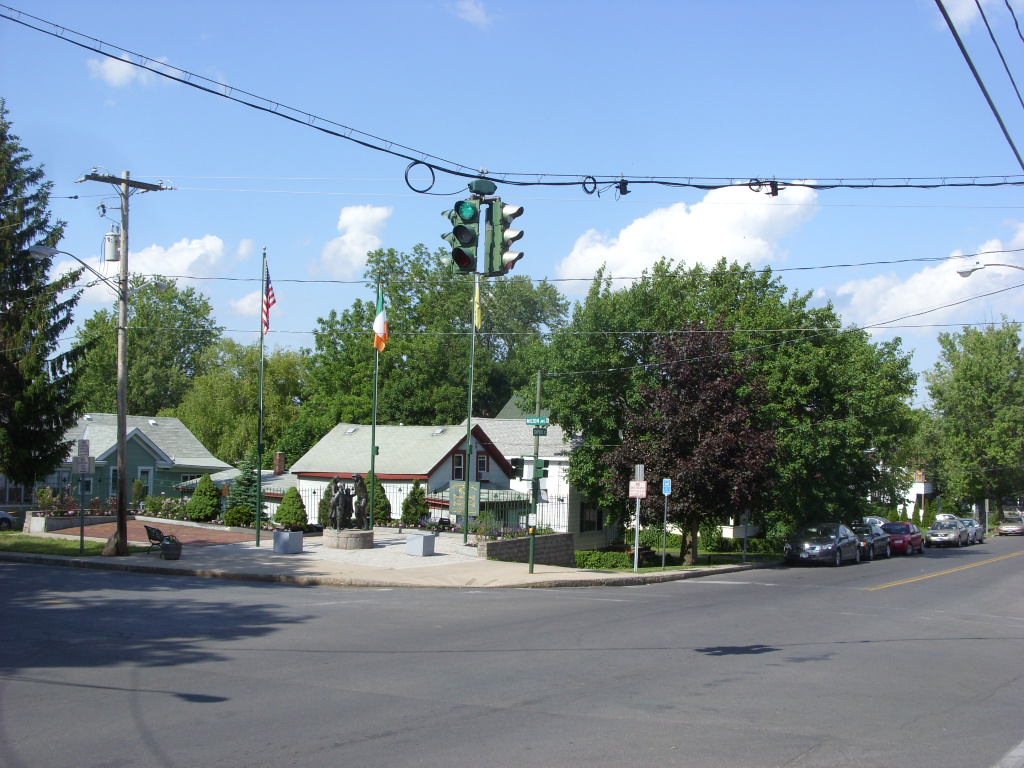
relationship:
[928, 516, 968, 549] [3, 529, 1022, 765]
car parked along street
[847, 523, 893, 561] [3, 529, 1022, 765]
car parked along street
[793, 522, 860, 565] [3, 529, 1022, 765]
car parked along street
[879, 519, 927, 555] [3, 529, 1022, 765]
car parked along street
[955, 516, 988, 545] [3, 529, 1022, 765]
car parked along street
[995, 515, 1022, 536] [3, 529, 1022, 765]
car parked along street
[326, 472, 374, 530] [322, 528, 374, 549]
statue on base